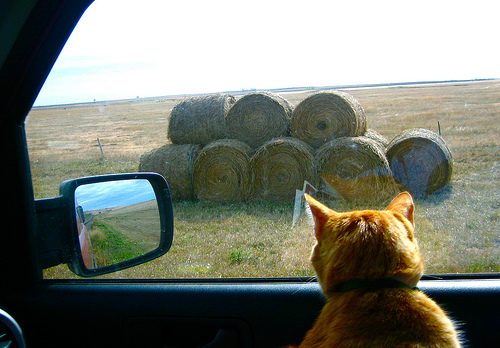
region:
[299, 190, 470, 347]
the back of an orange cat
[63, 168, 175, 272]
a cars side view mirror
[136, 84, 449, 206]
a pile of hay bales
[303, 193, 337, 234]
ear of a cat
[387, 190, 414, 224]
ear of a cat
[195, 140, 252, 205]
a bale of hay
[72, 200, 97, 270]
reflection of a car in a mirror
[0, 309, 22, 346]
section of a car's air vent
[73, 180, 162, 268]
a mirror on a car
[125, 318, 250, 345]
handle for a car door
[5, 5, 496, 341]
A cat staring out a car window at hay bales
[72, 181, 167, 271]
the car's side view mirror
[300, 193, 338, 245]
the cat's left ear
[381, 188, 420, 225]
the cat's right ear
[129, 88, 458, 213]
hay bales in the field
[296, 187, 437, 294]
the cat's head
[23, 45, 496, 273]
the car window's glass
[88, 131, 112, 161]
A fence post in the field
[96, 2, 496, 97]
Sky above the field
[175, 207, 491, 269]
Grass in front of the hay bales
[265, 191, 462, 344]
cat looks out window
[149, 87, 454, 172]
large bales of hay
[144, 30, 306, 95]
sky is blue and grey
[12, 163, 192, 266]
rear view mirror near cat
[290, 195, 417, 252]
cat has orange ears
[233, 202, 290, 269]
green grass near hay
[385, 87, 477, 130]
field is light brown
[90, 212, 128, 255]
green grass in mirror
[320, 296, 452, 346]
cat has long fur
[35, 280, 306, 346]
black vinyl on car door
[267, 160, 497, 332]
the cat is in the car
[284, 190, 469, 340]
the cat is looking out the window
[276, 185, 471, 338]
the cat's reflection is in the window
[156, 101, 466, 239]
bales of hay are outside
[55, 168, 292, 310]
the rearview mirror is black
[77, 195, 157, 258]
grass and dirt are in the rearview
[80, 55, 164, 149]
the sky is cloudy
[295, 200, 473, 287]
the orange cat is in the window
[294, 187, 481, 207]
the cat has pointy ears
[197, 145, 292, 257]
the hay is rolled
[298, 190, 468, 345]
a cat looking out a window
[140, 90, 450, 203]
a stack of round bales of hay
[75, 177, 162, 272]
reflection in the rear view mirror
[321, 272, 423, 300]
the collar of the cat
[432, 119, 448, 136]
a fence post behind the hay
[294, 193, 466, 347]
the back of a golden cat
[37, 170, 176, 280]
rear view mirror on a vehicle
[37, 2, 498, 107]
a white sky above the horizon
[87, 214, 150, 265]
reflection of green grass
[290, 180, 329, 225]
reflection of the cat's ear